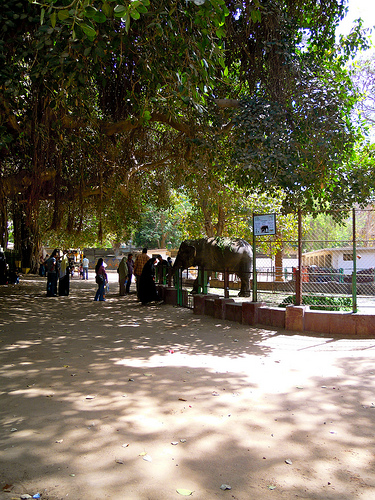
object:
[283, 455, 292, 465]
leaf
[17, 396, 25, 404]
dirt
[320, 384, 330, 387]
leaves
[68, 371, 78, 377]
leaves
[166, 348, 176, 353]
leaves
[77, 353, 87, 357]
leaves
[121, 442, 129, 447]
leaves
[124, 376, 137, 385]
leaf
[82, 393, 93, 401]
leaf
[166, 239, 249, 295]
elephant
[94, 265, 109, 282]
shirt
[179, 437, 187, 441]
leaf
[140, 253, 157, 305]
people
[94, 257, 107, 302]
woman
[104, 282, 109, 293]
water bottle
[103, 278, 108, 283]
hand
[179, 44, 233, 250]
trees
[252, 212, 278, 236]
sign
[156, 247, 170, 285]
people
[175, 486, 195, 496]
leaf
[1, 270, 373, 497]
ground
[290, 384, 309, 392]
leaf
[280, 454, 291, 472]
leaf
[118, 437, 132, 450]
leaf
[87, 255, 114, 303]
lady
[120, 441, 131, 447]
leaf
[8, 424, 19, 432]
leaf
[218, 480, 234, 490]
leaf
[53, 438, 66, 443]
leaf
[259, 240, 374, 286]
building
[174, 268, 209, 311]
gate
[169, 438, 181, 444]
leaf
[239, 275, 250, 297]
fat legs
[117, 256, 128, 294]
person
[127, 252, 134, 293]
person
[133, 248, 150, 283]
person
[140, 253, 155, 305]
person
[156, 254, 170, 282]
person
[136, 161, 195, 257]
trees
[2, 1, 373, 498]
park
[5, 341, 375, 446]
shadow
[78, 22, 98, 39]
leaf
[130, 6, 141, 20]
leaf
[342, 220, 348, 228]
leaf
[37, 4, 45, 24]
leaf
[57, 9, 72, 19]
leaf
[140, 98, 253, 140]
branch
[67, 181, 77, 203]
branch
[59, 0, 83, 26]
branch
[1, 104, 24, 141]
branch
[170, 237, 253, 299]
animal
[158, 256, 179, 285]
trunk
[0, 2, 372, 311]
tree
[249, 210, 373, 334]
fence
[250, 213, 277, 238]
sign board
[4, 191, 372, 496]
area